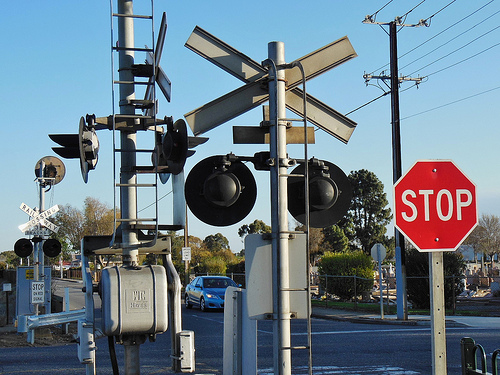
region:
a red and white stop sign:
[388, 150, 483, 260]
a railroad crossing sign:
[7, 198, 64, 241]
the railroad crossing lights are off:
[7, 234, 68, 261]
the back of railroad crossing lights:
[185, 147, 363, 245]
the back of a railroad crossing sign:
[182, 28, 364, 143]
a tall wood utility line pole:
[355, 7, 459, 177]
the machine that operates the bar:
[65, 222, 188, 351]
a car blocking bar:
[86, 5, 176, 215]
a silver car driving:
[180, 258, 245, 318]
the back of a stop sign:
[360, 244, 398, 313]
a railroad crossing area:
[4, 16, 446, 373]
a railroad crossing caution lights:
[17, 50, 404, 367]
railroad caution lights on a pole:
[33, 22, 430, 373]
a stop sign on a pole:
[386, 138, 499, 352]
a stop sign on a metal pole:
[368, 118, 499, 340]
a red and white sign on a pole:
[362, 98, 494, 363]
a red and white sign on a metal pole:
[374, 140, 496, 373]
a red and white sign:
[380, 133, 496, 273]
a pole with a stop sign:
[360, 118, 485, 374]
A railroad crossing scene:
[2, 2, 497, 373]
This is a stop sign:
[393, 157, 480, 374]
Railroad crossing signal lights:
[183, 152, 354, 230]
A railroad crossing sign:
[17, 201, 62, 233]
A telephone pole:
[361, 8, 430, 321]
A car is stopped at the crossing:
[183, 271, 244, 312]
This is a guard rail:
[14, 304, 91, 346]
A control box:
[99, 263, 170, 343]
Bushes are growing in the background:
[316, 248, 466, 310]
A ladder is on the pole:
[109, 1, 161, 251]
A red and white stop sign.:
[391, 161, 479, 253]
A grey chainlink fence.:
[199, 270, 499, 315]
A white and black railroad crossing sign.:
[14, 200, 60, 240]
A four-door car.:
[183, 274, 250, 319]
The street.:
[5, 267, 498, 372]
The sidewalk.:
[301, 294, 498, 330]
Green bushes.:
[162, 247, 474, 309]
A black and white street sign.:
[32, 281, 47, 303]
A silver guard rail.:
[15, 305, 95, 342]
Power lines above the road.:
[134, 0, 499, 213]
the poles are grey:
[21, 38, 453, 374]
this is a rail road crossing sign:
[13, 192, 66, 244]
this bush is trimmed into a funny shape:
[303, 243, 383, 313]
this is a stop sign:
[356, 237, 391, 272]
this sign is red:
[384, 148, 484, 268]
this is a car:
[176, 269, 250, 327]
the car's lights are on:
[198, 288, 251, 306]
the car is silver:
[170, 263, 242, 324]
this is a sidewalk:
[290, 290, 498, 339]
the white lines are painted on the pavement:
[275, 320, 452, 339]